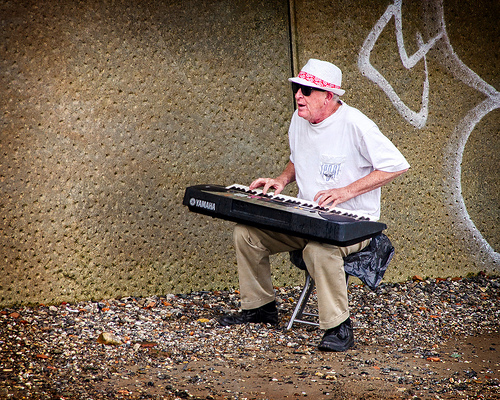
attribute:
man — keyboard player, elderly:
[212, 43, 414, 350]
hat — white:
[283, 51, 357, 108]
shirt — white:
[281, 96, 416, 234]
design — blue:
[316, 156, 347, 189]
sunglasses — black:
[287, 83, 331, 102]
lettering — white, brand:
[193, 195, 221, 216]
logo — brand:
[187, 196, 199, 211]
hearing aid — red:
[323, 91, 338, 104]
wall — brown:
[1, 1, 497, 314]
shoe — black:
[311, 317, 357, 355]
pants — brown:
[219, 218, 383, 337]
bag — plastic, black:
[283, 229, 402, 302]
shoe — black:
[213, 301, 288, 340]